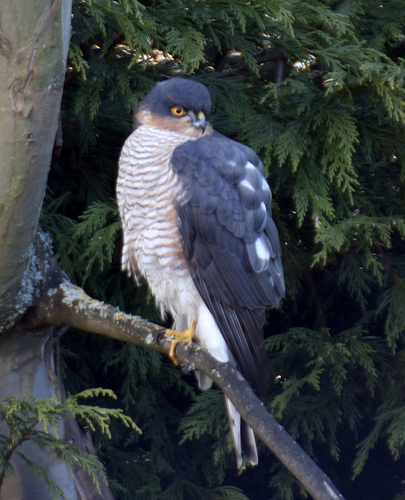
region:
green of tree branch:
[309, 96, 357, 154]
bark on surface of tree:
[0, 0, 72, 274]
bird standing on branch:
[116, 75, 286, 472]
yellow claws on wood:
[160, 330, 198, 364]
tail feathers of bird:
[225, 395, 259, 473]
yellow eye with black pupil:
[169, 104, 184, 115]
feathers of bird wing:
[183, 141, 286, 306]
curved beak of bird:
[192, 111, 209, 133]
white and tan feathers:
[114, 125, 180, 305]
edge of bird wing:
[212, 291, 287, 314]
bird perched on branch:
[102, 39, 309, 476]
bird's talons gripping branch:
[155, 319, 195, 372]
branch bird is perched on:
[58, 279, 336, 498]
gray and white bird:
[118, 70, 279, 476]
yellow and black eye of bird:
[170, 102, 187, 120]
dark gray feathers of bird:
[172, 137, 288, 395]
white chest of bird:
[117, 128, 219, 367]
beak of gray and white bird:
[186, 109, 209, 133]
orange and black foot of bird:
[156, 322, 197, 376]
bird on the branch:
[73, 79, 301, 322]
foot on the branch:
[145, 315, 200, 367]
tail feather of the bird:
[214, 414, 254, 453]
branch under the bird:
[268, 427, 330, 471]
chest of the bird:
[118, 151, 177, 216]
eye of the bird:
[163, 97, 190, 127]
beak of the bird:
[188, 109, 211, 134]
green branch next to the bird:
[78, 386, 132, 443]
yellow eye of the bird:
[164, 97, 188, 124]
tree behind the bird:
[286, 86, 372, 167]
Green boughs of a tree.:
[266, 13, 385, 165]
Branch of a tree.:
[199, 368, 286, 498]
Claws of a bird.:
[149, 312, 212, 373]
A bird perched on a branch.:
[88, 44, 300, 414]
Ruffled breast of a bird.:
[88, 134, 207, 324]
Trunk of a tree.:
[0, 5, 77, 78]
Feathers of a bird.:
[178, 131, 290, 384]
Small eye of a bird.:
[151, 96, 191, 134]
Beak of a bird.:
[183, 103, 211, 140]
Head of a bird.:
[137, 67, 227, 139]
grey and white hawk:
[120, 80, 283, 388]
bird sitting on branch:
[120, 78, 282, 396]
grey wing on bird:
[186, 141, 284, 294]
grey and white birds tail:
[220, 382, 259, 473]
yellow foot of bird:
[162, 320, 199, 362]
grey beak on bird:
[191, 113, 206, 131]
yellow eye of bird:
[171, 106, 183, 116]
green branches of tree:
[213, 74, 403, 498]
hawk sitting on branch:
[118, 78, 284, 469]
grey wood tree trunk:
[1, 1, 112, 499]